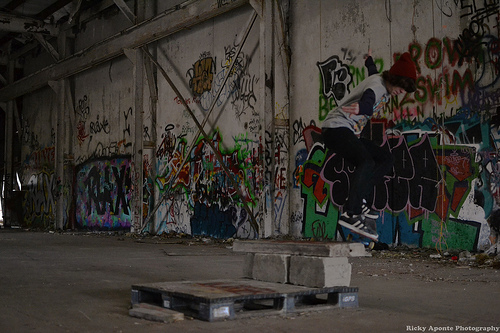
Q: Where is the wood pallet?
A: On the ground.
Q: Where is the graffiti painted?
A: On the wall.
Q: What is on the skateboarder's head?
A: A hat.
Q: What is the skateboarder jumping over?
A: Concrete.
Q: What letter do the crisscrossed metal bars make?
A: X.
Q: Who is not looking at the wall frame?
A: The skateboarder.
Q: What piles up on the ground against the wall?
A: Trash.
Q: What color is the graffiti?
A: Black, green, red, blue.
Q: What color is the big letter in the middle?
A: Black.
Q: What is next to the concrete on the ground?
A: Pallet.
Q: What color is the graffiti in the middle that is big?
A: Black.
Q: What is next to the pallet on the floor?
A: Concrete.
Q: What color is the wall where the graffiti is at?
A: White.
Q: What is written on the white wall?
A: Graffiti.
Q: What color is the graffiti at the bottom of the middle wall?
A: Blue.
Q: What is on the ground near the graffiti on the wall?
A: Trash.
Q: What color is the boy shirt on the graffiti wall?
A: White.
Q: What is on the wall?
A: Graffiti.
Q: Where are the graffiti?
A: On the wall.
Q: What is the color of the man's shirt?
A: Gray.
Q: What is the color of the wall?
A: White.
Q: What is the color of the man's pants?
A: Black.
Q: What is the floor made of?
A: Cement and concrete.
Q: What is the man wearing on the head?
A: A hat.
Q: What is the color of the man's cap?
A: Red.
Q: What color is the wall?
A: Tan.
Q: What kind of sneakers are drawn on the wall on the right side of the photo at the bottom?
A: Adidas.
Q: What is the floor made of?
A: Concrete cement.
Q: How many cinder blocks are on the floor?
A: Two.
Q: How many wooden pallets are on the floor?
A: One.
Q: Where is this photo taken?
A: Under a bridge.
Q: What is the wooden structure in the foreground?
A: A pallet.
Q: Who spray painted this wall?
A: Graffiti artists.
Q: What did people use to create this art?
A: Spray paint.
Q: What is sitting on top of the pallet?
A: Concrete blocks.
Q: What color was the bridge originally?
A: White.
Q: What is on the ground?
A: A pallet.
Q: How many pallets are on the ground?
A: One.